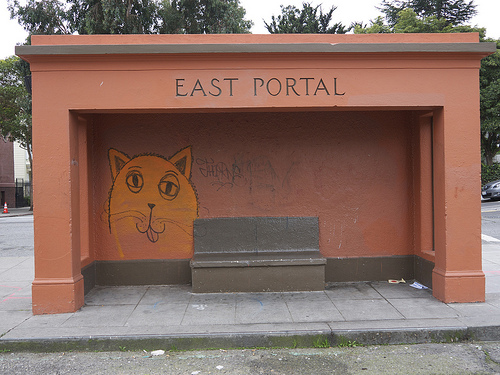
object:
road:
[0, 335, 499, 375]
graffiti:
[197, 147, 301, 196]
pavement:
[0, 215, 500, 340]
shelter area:
[16, 30, 498, 315]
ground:
[446, 181, 480, 226]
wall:
[80, 117, 432, 282]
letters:
[174, 77, 238, 96]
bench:
[190, 215, 326, 293]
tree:
[13, 0, 248, 32]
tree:
[257, 0, 345, 30]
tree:
[380, 1, 482, 31]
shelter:
[15, 29, 488, 314]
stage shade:
[12, 32, 496, 317]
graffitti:
[93, 150, 200, 258]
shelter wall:
[179, 132, 415, 257]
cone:
[168, 146, 193, 179]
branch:
[0, 41, 33, 158]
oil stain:
[242, 352, 350, 373]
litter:
[386, 278, 427, 291]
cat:
[96, 146, 200, 260]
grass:
[312, 334, 330, 348]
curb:
[229, 313, 456, 344]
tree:
[2, 57, 36, 177]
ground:
[270, 275, 438, 317]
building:
[17, 31, 493, 313]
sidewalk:
[0, 220, 32, 315]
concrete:
[0, 337, 499, 373]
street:
[0, 337, 498, 371]